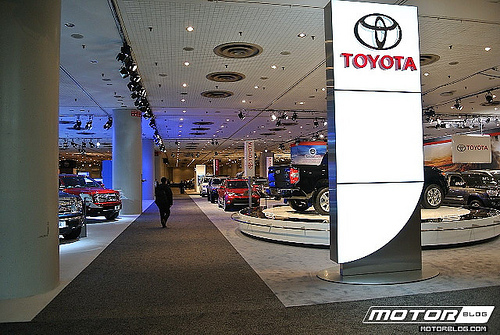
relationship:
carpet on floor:
[115, 234, 252, 311] [3, 188, 499, 333]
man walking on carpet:
[153, 176, 173, 229] [2, 190, 499, 333]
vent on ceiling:
[211, 37, 266, 60] [58, 0, 498, 165]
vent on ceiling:
[206, 69, 246, 82] [58, 0, 498, 165]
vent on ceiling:
[195, 85, 235, 103] [58, 0, 498, 165]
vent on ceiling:
[190, 118, 212, 127] [58, 0, 498, 165]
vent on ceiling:
[189, 129, 209, 139] [58, 0, 498, 165]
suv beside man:
[59, 174, 123, 220] [150, 174, 175, 229]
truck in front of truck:
[57, 184, 83, 243] [58, 170, 125, 221]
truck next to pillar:
[29, 130, 154, 267] [84, 65, 236, 267]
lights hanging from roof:
[101, 43, 172, 152] [57, 3, 498, 158]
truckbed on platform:
[267, 148, 330, 209] [237, 207, 324, 246]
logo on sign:
[338, 11, 418, 76] [321, 0, 426, 283]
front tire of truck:
[426, 186, 445, 210] [266, 147, 448, 210]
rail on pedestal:
[436, 215, 486, 232] [238, 204, 500, 250]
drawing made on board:
[351, 10, 401, 50] [321, 0, 428, 281]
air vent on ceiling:
[209, 43, 264, 60] [62, 4, 497, 146]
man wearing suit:
[153, 176, 173, 229] [154, 182, 173, 222]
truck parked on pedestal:
[260, 133, 440, 213] [238, 203, 498, 248]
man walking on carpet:
[151, 165, 186, 232] [30, 184, 283, 322]